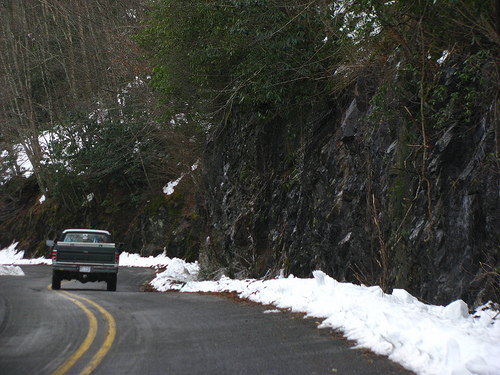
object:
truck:
[50, 224, 122, 290]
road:
[2, 256, 415, 374]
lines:
[47, 276, 115, 374]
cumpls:
[166, 264, 499, 374]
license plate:
[77, 268, 94, 277]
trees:
[1, 5, 146, 163]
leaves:
[1, 0, 149, 175]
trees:
[132, 10, 496, 287]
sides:
[127, 245, 497, 368]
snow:
[1, 235, 57, 262]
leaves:
[147, 2, 495, 261]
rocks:
[195, 59, 499, 303]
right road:
[61, 252, 406, 374]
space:
[56, 243, 114, 276]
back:
[56, 231, 124, 279]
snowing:
[9, 246, 391, 373]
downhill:
[5, 226, 187, 277]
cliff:
[1, 1, 214, 224]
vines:
[374, 107, 422, 280]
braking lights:
[48, 249, 123, 269]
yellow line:
[46, 276, 117, 374]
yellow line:
[81, 291, 114, 374]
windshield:
[59, 229, 110, 245]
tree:
[149, 2, 340, 257]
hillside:
[15, 3, 495, 295]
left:
[6, 1, 71, 240]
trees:
[38, 107, 118, 251]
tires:
[49, 275, 120, 294]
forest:
[7, 8, 496, 290]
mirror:
[42, 238, 58, 251]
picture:
[1, 4, 499, 367]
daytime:
[3, 3, 499, 367]